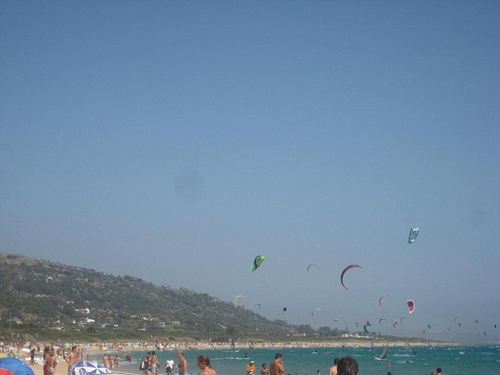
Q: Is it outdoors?
A: Yes, it is outdoors.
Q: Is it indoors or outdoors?
A: It is outdoors.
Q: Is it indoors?
A: No, it is outdoors.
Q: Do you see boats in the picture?
A: No, there are no boats.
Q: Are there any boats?
A: No, there are no boats.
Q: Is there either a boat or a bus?
A: No, there are no boats or buses.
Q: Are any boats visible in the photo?
A: No, there are no boats.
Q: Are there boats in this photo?
A: No, there are no boats.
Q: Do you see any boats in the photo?
A: No, there are no boats.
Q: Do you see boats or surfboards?
A: No, there are no boats or surfboards.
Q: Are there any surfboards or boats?
A: No, there are no boats or surfboards.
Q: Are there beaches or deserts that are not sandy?
A: No, there is a beach but it is sandy.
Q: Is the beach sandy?
A: Yes, the beach is sandy.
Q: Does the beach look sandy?
A: Yes, the beach is sandy.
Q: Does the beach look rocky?
A: No, the beach is sandy.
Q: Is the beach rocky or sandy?
A: The beach is sandy.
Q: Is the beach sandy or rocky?
A: The beach is sandy.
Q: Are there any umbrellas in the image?
A: Yes, there are umbrellas.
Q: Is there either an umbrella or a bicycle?
A: Yes, there are umbrellas.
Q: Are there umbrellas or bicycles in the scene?
A: Yes, there are umbrellas.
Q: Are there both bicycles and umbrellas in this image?
A: No, there are umbrellas but no bicycles.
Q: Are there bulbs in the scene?
A: No, there are no bulbs.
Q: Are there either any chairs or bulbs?
A: No, there are no bulbs or chairs.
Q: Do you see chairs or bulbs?
A: No, there are no bulbs or chairs.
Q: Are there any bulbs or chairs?
A: No, there are no bulbs or chairs.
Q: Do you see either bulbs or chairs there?
A: No, there are no bulbs or chairs.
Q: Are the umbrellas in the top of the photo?
A: No, the umbrellas are in the bottom of the image.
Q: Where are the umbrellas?
A: The umbrellas are on the beach.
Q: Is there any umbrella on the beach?
A: Yes, there are umbrellas on the beach.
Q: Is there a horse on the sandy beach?
A: No, there are umbrellas on the beach.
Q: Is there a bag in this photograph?
A: No, there are no bags.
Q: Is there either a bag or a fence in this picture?
A: No, there are no bags or fences.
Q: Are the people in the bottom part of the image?
A: Yes, the people are in the bottom of the image.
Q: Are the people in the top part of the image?
A: No, the people are in the bottom of the image.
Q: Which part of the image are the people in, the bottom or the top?
A: The people are in the bottom of the image.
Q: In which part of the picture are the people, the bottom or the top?
A: The people are in the bottom of the image.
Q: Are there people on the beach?
A: Yes, there are people on the beach.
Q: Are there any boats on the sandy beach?
A: No, there are people on the beach.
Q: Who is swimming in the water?
A: The people are swimming in the water.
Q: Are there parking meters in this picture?
A: No, there are no parking meters.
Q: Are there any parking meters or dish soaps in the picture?
A: No, there are no parking meters or dish soaps.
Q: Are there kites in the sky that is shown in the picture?
A: Yes, there are kites in the sky.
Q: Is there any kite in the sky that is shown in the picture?
A: Yes, there are kites in the sky.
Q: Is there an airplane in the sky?
A: No, there are kites in the sky.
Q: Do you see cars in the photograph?
A: No, there are no cars.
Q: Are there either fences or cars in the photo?
A: No, there are no cars or fences.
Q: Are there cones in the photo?
A: No, there are no cones.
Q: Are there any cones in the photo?
A: No, there are no cones.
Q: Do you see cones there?
A: No, there are no cones.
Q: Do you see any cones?
A: No, there are no cones.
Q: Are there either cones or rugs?
A: No, there are no cones or rugs.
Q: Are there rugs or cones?
A: No, there are no cones or rugs.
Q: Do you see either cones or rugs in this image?
A: No, there are no cones or rugs.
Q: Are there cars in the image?
A: No, there are no cars.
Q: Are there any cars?
A: No, there are no cars.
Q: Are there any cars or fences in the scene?
A: No, there are no cars or fences.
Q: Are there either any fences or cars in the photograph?
A: No, there are no cars or fences.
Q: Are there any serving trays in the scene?
A: No, there are no serving trays.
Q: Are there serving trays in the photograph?
A: No, there are no serving trays.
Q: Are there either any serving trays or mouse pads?
A: No, there are no serving trays or mouse pads.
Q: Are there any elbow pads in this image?
A: No, there are no elbow pads.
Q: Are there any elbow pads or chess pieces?
A: No, there are no elbow pads or chess pieces.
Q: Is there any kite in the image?
A: Yes, there is a kite.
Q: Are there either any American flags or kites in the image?
A: Yes, there is a kite.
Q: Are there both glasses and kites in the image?
A: No, there is a kite but no glasses.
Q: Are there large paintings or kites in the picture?
A: Yes, there is a large kite.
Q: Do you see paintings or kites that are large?
A: Yes, the kite is large.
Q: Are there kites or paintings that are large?
A: Yes, the kite is large.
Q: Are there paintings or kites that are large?
A: Yes, the kite is large.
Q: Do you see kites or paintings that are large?
A: Yes, the kite is large.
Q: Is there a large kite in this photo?
A: Yes, there is a large kite.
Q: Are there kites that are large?
A: Yes, there is a kite that is large.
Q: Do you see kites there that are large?
A: Yes, there is a kite that is large.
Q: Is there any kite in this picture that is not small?
A: Yes, there is a large kite.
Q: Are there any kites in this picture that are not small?
A: Yes, there is a large kite.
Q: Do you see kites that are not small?
A: Yes, there is a large kite.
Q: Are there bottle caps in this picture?
A: No, there are no bottle caps.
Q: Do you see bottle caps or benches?
A: No, there are no bottle caps or benches.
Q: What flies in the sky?
A: The kite flies in the sky.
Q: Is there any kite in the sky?
A: Yes, there is a kite in the sky.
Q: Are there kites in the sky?
A: Yes, there is a kite in the sky.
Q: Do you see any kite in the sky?
A: Yes, there is a kite in the sky.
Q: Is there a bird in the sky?
A: No, there is a kite in the sky.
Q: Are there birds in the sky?
A: No, there is a kite in the sky.